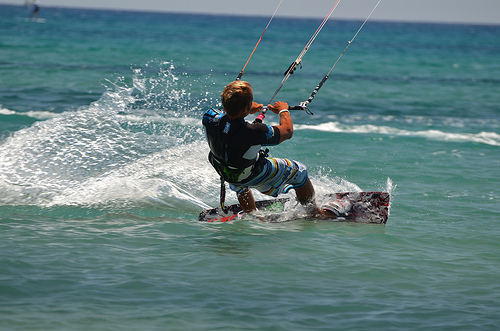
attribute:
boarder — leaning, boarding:
[200, 82, 317, 214]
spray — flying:
[0, 60, 208, 216]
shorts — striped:
[232, 156, 308, 198]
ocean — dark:
[3, 225, 500, 329]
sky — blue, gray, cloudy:
[2, 2, 499, 28]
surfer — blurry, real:
[23, 2, 46, 23]